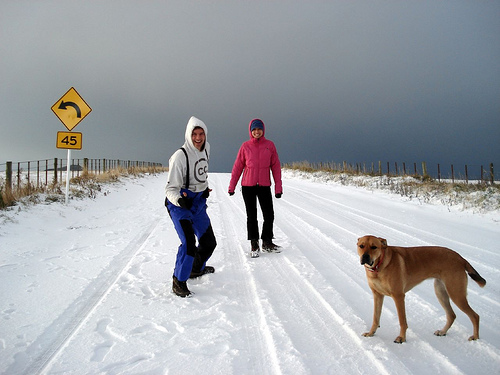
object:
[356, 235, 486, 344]
dog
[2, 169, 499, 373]
snow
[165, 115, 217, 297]
man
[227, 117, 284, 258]
woman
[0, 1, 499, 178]
sky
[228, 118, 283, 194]
jacket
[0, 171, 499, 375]
ground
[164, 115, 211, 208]
jacket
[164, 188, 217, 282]
pants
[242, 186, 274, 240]
pants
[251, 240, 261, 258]
boots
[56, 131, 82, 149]
sign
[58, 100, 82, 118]
arrow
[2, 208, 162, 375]
tire track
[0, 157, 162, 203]
fence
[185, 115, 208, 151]
hood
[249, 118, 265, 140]
hood and hat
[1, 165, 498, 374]
snow covered road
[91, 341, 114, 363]
footprint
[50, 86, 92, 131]
signs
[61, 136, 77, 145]
45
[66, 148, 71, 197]
pole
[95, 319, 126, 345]
footprint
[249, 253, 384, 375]
tire track